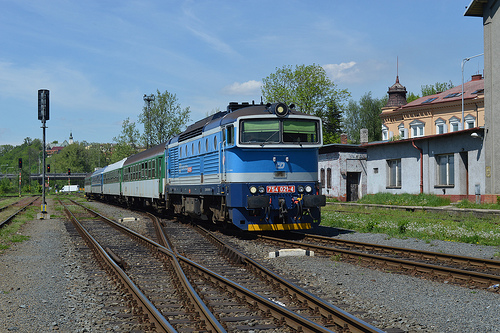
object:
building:
[377, 56, 482, 142]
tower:
[384, 58, 407, 104]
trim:
[246, 220, 316, 235]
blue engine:
[166, 95, 326, 230]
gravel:
[111, 213, 398, 331]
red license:
[264, 185, 298, 195]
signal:
[34, 85, 52, 125]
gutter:
[407, 137, 429, 195]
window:
[230, 114, 280, 144]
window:
[278, 110, 323, 145]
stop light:
[14, 154, 26, 196]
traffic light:
[15, 155, 25, 170]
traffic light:
[42, 160, 53, 172]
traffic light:
[65, 167, 74, 181]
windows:
[117, 160, 162, 180]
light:
[34, 84, 52, 221]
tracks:
[205, 217, 499, 293]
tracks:
[147, 210, 382, 332]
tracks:
[4, 187, 41, 234]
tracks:
[0, 185, 498, 332]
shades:
[248, 117, 310, 134]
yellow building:
[378, 55, 483, 138]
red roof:
[406, 77, 485, 107]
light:
[35, 88, 51, 120]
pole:
[35, 124, 52, 221]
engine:
[163, 101, 330, 236]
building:
[318, 125, 488, 207]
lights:
[220, 155, 332, 215]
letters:
[262, 180, 307, 197]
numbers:
[266, 179, 309, 197]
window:
[151, 160, 156, 177]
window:
[146, 160, 153, 180]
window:
[139, 162, 144, 179]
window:
[130, 165, 137, 180]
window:
[124, 167, 131, 181]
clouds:
[228, 74, 265, 98]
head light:
[265, 95, 300, 125]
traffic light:
[36, 87, 53, 121]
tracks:
[118, 204, 325, 307]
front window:
[239, 116, 321, 147]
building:
[346, 123, 498, 211]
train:
[94, 95, 336, 247]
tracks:
[72, 204, 346, 331]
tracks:
[34, 207, 474, 330]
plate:
[260, 174, 317, 194]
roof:
[388, 77, 489, 112]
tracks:
[178, 222, 498, 331]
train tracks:
[68, 189, 498, 330]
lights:
[8, 85, 78, 185]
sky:
[2, 1, 482, 142]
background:
[2, 59, 483, 187]